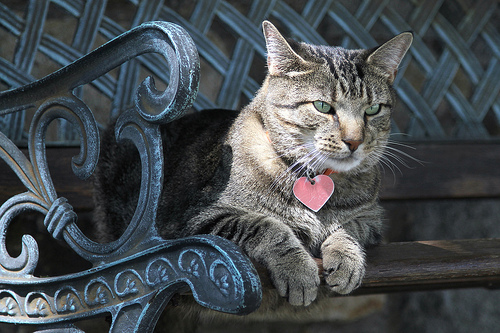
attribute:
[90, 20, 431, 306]
tabby cat — heart, multi-colored, in sun, sitting, grey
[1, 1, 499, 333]
bench — wrought iron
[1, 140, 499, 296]
seat — wood, wooden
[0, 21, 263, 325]
arm — wrought-iron, iron, metal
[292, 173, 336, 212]
tag — heart-shaped, red, metal, heart shaped, heart, heart shape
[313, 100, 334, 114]
eye — green, dull green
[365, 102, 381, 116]
eye — green, dull green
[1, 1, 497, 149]
back — iron